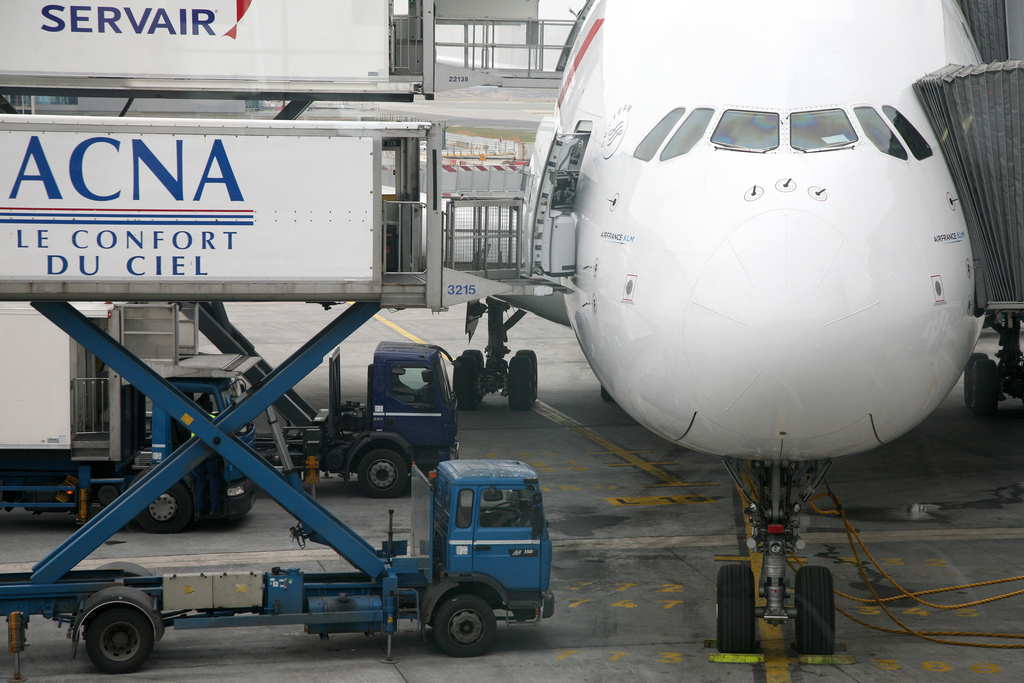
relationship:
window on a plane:
[630, 100, 689, 155] [433, 5, 993, 664]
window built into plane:
[709, 106, 783, 154] [494, 1, 992, 660]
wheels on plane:
[710, 551, 845, 664] [433, 5, 993, 664]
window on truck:
[476, 480, 529, 533] [407, 452, 567, 664]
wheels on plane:
[710, 551, 845, 664] [494, 1, 992, 660]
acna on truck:
[8, 130, 248, 211] [4, 111, 575, 676]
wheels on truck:
[70, 558, 172, 679] [4, 111, 575, 676]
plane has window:
[494, 1, 992, 660] [710, 100, 784, 170]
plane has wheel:
[494, 1, 992, 660] [788, 552, 847, 665]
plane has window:
[494, 1, 992, 660] [840, 100, 916, 181]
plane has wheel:
[494, 1, 992, 660] [714, 552, 767, 661]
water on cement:
[557, 549, 694, 647] [4, 268, 992, 679]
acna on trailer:
[8, 136, 246, 201] [4, 104, 454, 306]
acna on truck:
[8, 136, 246, 201] [4, 111, 575, 676]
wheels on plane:
[442, 305, 546, 416] [433, 5, 993, 664]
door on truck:
[470, 487, 538, 587] [6, 439, 560, 675]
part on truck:
[217, 1, 267, 51] [3, 5, 446, 111]